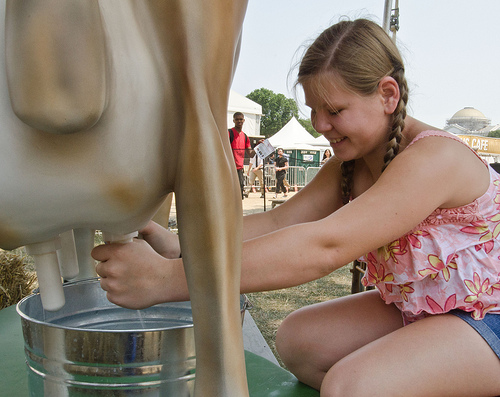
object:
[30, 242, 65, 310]
udder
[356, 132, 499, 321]
shirt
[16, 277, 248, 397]
bucket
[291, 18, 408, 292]
hair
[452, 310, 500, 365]
shorts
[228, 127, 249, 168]
top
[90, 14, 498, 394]
girl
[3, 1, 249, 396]
cow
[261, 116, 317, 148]
tent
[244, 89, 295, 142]
tree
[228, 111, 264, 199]
man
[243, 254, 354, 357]
grass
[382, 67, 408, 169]
braid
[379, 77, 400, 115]
ear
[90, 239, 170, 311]
hand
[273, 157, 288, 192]
outfit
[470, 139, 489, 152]
writting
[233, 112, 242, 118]
hair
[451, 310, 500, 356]
jeans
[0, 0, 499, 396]
photo